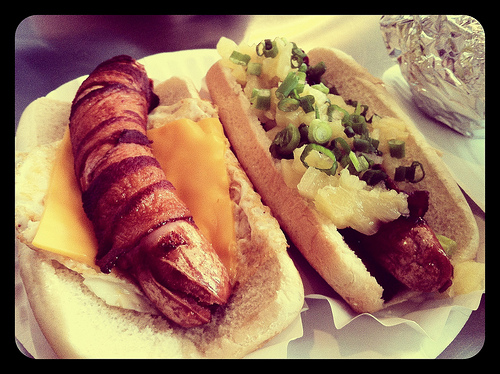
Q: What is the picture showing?
A: Food.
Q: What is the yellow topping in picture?
A: Cheese.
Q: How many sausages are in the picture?
A: Two.